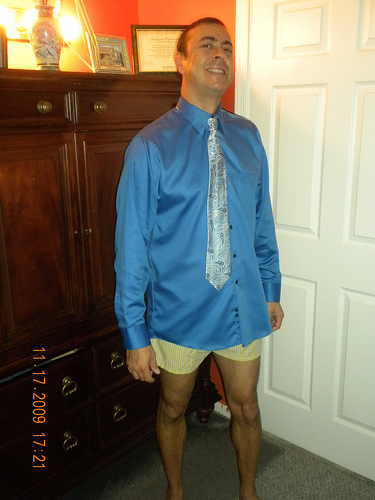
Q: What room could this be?
A: It is a bedroom.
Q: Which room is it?
A: It is a bedroom.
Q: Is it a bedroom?
A: Yes, it is a bedroom.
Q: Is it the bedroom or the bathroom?
A: It is the bedroom.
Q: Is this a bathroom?
A: No, it is a bedroom.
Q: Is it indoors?
A: Yes, it is indoors.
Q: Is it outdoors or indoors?
A: It is indoors.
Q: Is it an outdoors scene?
A: No, it is indoors.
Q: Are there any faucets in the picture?
A: No, there are no faucets.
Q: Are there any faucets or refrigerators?
A: No, there are no faucets or refrigerators.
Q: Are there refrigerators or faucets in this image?
A: No, there are no faucets or refrigerators.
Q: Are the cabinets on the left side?
A: Yes, the cabinets are on the left of the image.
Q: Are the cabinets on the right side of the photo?
A: No, the cabinets are on the left of the image.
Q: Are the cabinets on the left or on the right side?
A: The cabinets are on the left of the image.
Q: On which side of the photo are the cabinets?
A: The cabinets are on the left of the image.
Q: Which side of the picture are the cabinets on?
A: The cabinets are on the left of the image.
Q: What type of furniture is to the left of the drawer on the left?
A: The pieces of furniture are cabinets.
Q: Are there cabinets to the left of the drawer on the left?
A: Yes, there are cabinets to the left of the drawer.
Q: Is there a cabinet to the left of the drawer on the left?
A: Yes, there are cabinets to the left of the drawer.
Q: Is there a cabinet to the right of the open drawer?
A: No, the cabinets are to the left of the drawer.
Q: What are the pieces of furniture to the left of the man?
A: The pieces of furniture are cabinets.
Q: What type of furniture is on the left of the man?
A: The pieces of furniture are cabinets.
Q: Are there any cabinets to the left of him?
A: Yes, there are cabinets to the left of the man.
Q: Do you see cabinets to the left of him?
A: Yes, there are cabinets to the left of the man.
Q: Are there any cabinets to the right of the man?
A: No, the cabinets are to the left of the man.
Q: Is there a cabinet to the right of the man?
A: No, the cabinets are to the left of the man.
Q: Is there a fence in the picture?
A: No, there are no fences.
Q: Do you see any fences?
A: No, there are no fences.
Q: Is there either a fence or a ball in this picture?
A: No, there are no fences or balls.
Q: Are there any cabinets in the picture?
A: Yes, there is a cabinet.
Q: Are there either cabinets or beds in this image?
A: Yes, there is a cabinet.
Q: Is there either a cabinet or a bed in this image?
A: Yes, there is a cabinet.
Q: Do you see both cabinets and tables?
A: No, there is a cabinet but no tables.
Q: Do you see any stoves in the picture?
A: No, there are no stoves.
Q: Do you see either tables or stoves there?
A: No, there are no stoves or tables.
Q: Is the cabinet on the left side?
A: Yes, the cabinet is on the left of the image.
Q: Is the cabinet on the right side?
A: No, the cabinet is on the left of the image.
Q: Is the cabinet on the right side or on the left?
A: The cabinet is on the left of the image.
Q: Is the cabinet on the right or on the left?
A: The cabinet is on the left of the image.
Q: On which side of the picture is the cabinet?
A: The cabinet is on the left of the image.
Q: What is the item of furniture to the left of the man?
A: The piece of furniture is a cabinet.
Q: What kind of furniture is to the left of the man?
A: The piece of furniture is a cabinet.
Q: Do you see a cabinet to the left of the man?
A: Yes, there is a cabinet to the left of the man.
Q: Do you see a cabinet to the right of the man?
A: No, the cabinet is to the left of the man.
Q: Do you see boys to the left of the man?
A: No, there is a cabinet to the left of the man.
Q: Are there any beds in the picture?
A: No, there are no beds.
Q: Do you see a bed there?
A: No, there are no beds.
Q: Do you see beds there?
A: No, there are no beds.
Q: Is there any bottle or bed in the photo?
A: No, there are no beds or bottles.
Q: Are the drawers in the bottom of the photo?
A: Yes, the drawers are in the bottom of the image.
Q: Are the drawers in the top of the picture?
A: No, the drawers are in the bottom of the image.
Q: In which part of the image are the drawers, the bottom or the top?
A: The drawers are in the bottom of the image.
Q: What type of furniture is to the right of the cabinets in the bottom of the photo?
A: The pieces of furniture are drawers.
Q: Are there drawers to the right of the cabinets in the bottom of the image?
A: Yes, there are drawers to the right of the cabinets.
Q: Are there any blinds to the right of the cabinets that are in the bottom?
A: No, there are drawers to the right of the cabinets.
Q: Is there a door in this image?
A: Yes, there is a door.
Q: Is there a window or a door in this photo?
A: Yes, there is a door.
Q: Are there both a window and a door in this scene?
A: No, there is a door but no windows.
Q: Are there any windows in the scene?
A: No, there are no windows.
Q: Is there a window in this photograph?
A: No, there are no windows.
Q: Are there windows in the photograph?
A: No, there are no windows.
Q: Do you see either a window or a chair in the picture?
A: No, there are no windows or chairs.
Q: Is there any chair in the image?
A: No, there are no chairs.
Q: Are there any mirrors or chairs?
A: No, there are no chairs or mirrors.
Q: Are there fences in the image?
A: No, there are no fences.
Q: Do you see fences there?
A: No, there are no fences.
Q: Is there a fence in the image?
A: No, there are no fences.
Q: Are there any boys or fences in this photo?
A: No, there are no fences or boys.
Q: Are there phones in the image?
A: No, there are no phones.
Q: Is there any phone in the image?
A: No, there are no phones.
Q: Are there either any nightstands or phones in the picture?
A: No, there are no phones or nightstands.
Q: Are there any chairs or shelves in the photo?
A: No, there are no chairs or shelves.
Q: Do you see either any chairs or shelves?
A: No, there are no chairs or shelves.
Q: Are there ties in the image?
A: Yes, there is a tie.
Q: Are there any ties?
A: Yes, there is a tie.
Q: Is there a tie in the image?
A: Yes, there is a tie.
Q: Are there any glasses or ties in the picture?
A: Yes, there is a tie.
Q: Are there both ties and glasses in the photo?
A: Yes, there are both a tie and glasses.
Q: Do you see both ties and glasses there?
A: Yes, there are both a tie and glasses.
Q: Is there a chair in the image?
A: No, there are no chairs.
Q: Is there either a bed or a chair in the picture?
A: No, there are no chairs or beds.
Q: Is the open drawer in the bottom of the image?
A: Yes, the drawer is in the bottom of the image.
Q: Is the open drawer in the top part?
A: No, the drawer is in the bottom of the image.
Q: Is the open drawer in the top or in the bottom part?
A: The drawer is in the bottom of the image.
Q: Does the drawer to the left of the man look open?
A: Yes, the drawer is open.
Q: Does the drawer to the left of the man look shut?
A: No, the drawer is open.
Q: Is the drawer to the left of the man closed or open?
A: The drawer is open.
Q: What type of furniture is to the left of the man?
A: The piece of furniture is a drawer.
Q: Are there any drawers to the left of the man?
A: Yes, there is a drawer to the left of the man.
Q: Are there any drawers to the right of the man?
A: No, the drawer is to the left of the man.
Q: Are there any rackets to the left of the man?
A: No, there is a drawer to the left of the man.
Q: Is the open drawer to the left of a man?
A: Yes, the drawer is to the left of a man.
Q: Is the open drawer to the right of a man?
A: No, the drawer is to the left of a man.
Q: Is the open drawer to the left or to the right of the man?
A: The drawer is to the left of the man.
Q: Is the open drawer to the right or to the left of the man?
A: The drawer is to the left of the man.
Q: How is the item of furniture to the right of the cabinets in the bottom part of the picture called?
A: The piece of furniture is a drawer.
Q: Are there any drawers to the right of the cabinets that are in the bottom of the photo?
A: Yes, there is a drawer to the right of the cabinets.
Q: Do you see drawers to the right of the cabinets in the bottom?
A: Yes, there is a drawer to the right of the cabinets.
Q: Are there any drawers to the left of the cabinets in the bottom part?
A: No, the drawer is to the right of the cabinets.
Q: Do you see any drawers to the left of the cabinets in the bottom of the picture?
A: No, the drawer is to the right of the cabinets.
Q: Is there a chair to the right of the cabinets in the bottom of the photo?
A: No, there is a drawer to the right of the cabinets.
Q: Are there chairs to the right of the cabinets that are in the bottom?
A: No, there is a drawer to the right of the cabinets.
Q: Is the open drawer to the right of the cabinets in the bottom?
A: Yes, the drawer is to the right of the cabinets.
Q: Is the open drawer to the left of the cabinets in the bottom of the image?
A: No, the drawer is to the right of the cabinets.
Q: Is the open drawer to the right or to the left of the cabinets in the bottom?
A: The drawer is to the right of the cabinets.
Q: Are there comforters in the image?
A: No, there are no comforters.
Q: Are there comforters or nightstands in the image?
A: No, there are no comforters or nightstands.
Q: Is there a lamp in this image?
A: Yes, there is a lamp.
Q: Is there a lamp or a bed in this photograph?
A: Yes, there is a lamp.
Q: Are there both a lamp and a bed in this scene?
A: No, there is a lamp but no beds.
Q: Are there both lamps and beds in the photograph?
A: No, there is a lamp but no beds.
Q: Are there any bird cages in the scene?
A: No, there are no bird cages.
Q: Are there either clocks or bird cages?
A: No, there are no bird cages or clocks.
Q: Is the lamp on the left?
A: Yes, the lamp is on the left of the image.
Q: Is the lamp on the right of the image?
A: No, the lamp is on the left of the image.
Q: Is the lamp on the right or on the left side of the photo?
A: The lamp is on the left of the image.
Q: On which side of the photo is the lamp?
A: The lamp is on the left of the image.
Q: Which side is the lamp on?
A: The lamp is on the left of the image.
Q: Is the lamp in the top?
A: Yes, the lamp is in the top of the image.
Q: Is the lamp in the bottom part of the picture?
A: No, the lamp is in the top of the image.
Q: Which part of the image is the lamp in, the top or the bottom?
A: The lamp is in the top of the image.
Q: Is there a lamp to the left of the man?
A: Yes, there is a lamp to the left of the man.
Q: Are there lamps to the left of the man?
A: Yes, there is a lamp to the left of the man.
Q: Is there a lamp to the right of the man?
A: No, the lamp is to the left of the man.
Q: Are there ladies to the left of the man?
A: No, there is a lamp to the left of the man.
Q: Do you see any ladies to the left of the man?
A: No, there is a lamp to the left of the man.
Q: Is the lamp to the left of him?
A: Yes, the lamp is to the left of a man.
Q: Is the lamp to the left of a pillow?
A: No, the lamp is to the left of a man.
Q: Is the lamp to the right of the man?
A: No, the lamp is to the left of the man.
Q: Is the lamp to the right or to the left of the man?
A: The lamp is to the left of the man.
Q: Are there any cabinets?
A: Yes, there is a cabinet.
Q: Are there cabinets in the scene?
A: Yes, there is a cabinet.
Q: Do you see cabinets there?
A: Yes, there is a cabinet.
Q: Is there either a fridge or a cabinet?
A: Yes, there is a cabinet.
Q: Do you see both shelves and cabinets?
A: No, there is a cabinet but no shelves.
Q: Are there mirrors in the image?
A: No, there are no mirrors.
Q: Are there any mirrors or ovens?
A: No, there are no mirrors or ovens.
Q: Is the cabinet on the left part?
A: Yes, the cabinet is on the left of the image.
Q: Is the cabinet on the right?
A: No, the cabinet is on the left of the image.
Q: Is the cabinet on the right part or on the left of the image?
A: The cabinet is on the left of the image.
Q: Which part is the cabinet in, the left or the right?
A: The cabinet is on the left of the image.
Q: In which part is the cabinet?
A: The cabinet is on the left of the image.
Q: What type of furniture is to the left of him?
A: The piece of furniture is a cabinet.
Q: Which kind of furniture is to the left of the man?
A: The piece of furniture is a cabinet.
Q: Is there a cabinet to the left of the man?
A: Yes, there is a cabinet to the left of the man.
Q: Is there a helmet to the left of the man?
A: No, there is a cabinet to the left of the man.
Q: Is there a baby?
A: No, there are no babies.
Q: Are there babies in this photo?
A: No, there are no babies.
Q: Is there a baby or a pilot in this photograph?
A: No, there are no babies or pilots.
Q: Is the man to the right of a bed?
A: No, the man is to the right of a cabinet.